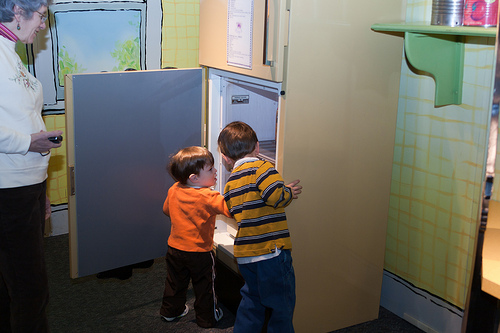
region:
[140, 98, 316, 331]
Two young children peering into a fridge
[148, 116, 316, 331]
Two young children peering into a fridge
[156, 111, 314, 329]
Two young children peering into a fridge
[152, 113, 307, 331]
Two young children peering into a fridge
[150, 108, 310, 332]
Two young children peering into a fridge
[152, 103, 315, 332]
Two young children peering into a fridge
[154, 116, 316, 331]
Two young children peering into a fridge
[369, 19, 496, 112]
a green shelf on a wall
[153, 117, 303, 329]
two little boys standing in front of a fridge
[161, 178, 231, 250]
an orange shirt on a little boy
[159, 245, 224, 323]
brown pants with a white stripe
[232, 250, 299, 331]
blue pants on a boy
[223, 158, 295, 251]
a yellow shirt with grey and black stripes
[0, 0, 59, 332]
a woman looking at two little boys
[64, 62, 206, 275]
an open refrigerator door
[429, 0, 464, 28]
a metal can on a shelf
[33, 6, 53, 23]
glasses on a woman's face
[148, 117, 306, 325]
a couple of boys in a refrigerator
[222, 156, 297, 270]
a yellow strip shirt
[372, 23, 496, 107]
a green shelf on a wall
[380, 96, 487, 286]
a checkered yellow wall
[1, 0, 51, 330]
a lady watching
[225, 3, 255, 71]
a paper on a refrigerator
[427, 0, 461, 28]
a silver can on a shelf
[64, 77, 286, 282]
a open door on a refrigerator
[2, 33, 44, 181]
a white shirt on a lady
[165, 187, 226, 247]
a orange shirt on a boy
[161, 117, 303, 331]
two little boys in a refrigerator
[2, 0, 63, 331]
an older woman watching little boys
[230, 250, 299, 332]
blue jeans on a little boy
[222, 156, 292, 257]
a yellow shirt with white and black stripes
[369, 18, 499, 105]
a green shelf on a wall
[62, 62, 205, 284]
the open door of a refrigerator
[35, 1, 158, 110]
a window drawn on a wall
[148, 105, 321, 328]
Two kids in the foreground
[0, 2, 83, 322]
An older woman in the foreground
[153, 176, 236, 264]
Young kid is wearing an orange shirt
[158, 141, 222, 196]
A side view of a kid's head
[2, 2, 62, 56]
Woman is wearing eyeglasses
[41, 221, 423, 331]
Carpet is covering the floor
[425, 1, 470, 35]
A tin can in the foreground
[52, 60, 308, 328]
Refrigerator door is open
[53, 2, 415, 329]
Refrigerator is tan in color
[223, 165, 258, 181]
stripe on the yellow shirt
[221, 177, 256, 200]
stripe on the yellow shirt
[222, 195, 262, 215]
stripe on the yellow shirt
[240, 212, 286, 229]
stripe on the yellow shirt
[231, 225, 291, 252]
stripe on the yellow shirt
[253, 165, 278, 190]
stripe on the yellow shirt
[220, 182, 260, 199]
stripe on the yellow shirt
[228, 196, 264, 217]
stripe on the yellow shirt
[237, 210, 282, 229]
stripe on the yellow shirt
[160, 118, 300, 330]
two little boys looking in the fridge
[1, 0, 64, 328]
woman watching the to boys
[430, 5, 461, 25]
tin can on the green shelf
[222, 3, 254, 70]
white paper on the fridge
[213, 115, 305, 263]
boy is wearing striped shirt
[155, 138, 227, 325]
boy is wearing a orange shirt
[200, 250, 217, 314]
white stripe on the pants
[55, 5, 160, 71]
fake window on the wall